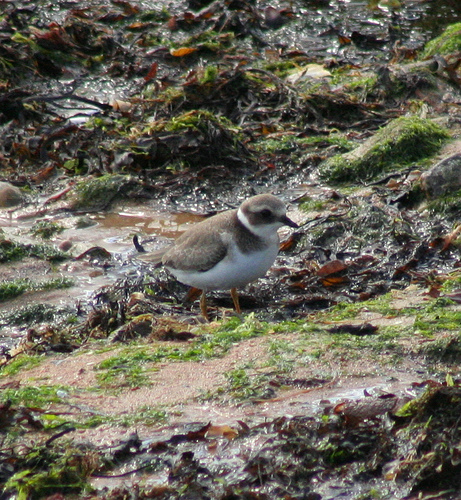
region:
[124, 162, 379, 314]
a gray and white bird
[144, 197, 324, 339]
a gray and white bird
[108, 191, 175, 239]
a brown puddle of water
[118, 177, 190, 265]
a brown puddle of water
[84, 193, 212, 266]
a brown puddle of water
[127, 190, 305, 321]
The bird on the ground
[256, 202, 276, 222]
The right eye of the bird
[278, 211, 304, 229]
The bird's black beak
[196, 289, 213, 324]
The right leg of the bird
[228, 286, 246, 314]
The left leg of the bird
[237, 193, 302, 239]
The head of the bird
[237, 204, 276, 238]
The white collar on the bird's neck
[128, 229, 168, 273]
The tail of the small bird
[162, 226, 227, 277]
The right wing of the bird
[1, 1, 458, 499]
The water covered ground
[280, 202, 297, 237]
Bird has black beak.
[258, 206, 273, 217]
Bird has black eye.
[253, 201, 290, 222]
White stripe around bird's face.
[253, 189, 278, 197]
Bird has gray head.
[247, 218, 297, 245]
Bird has white neck.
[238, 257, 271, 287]
Bird has white chest.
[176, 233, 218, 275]
Bird has gray wing.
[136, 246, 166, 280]
Bird has gray tail feathers.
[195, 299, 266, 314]
Bird has brown legs.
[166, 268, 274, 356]
Bird is standing on wet ground.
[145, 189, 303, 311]
bird resting on ground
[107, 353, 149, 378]
patch of green space on ground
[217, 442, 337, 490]
brownish space on ground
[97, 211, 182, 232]
water that is murky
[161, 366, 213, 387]
area where no grass lies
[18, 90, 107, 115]
a piece of branch on the ground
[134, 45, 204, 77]
shades of leaves on ground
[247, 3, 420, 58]
piles of wet leaves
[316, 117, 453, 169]
thick clump of grass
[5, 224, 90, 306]
patches of grass in murky area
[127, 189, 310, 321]
a bird color white and brown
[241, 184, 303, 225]
top of head of bird is brown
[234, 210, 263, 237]
neck of bird is white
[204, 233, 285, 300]
breast of bird is white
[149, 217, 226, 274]
wing of bird is brown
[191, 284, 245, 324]
two orange legs of bird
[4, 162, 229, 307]
a puddle of water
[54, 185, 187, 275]
water in the puddle is dirty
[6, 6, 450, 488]
bird stand on a muddy surface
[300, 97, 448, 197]
moss grows on stone